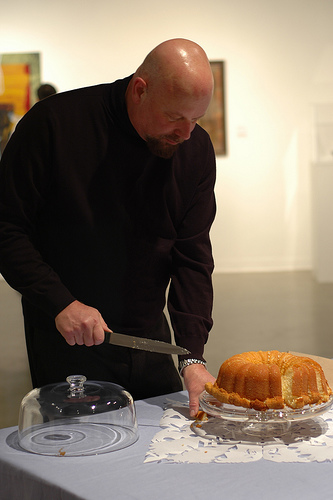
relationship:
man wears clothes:
[1, 37, 221, 422] [1, 74, 217, 425]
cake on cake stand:
[203, 349, 332, 412] [198, 390, 332, 435]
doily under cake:
[145, 396, 333, 465] [203, 349, 332, 412]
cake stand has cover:
[198, 390, 332, 435] [18, 374, 139, 456]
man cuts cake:
[1, 37, 221, 422] [203, 349, 332, 412]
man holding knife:
[1, 37, 221, 422] [104, 331, 190, 357]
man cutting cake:
[1, 37, 221, 422] [203, 349, 332, 412]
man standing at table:
[1, 37, 221, 422] [1, 381, 331, 498]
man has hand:
[1, 37, 221, 422] [53, 299, 115, 346]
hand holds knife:
[53, 299, 115, 346] [104, 331, 190, 357]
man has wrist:
[1, 37, 221, 422] [176, 356, 210, 376]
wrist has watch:
[176, 356, 210, 376] [178, 358, 206, 374]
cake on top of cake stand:
[203, 349, 332, 412] [198, 390, 332, 435]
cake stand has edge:
[198, 390, 332, 435] [227, 409, 327, 423]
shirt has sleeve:
[2, 71, 217, 365] [167, 130, 216, 365]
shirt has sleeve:
[2, 71, 217, 365] [1, 97, 80, 322]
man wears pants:
[1, 37, 221, 422] [21, 295, 184, 423]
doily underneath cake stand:
[145, 396, 333, 465] [198, 390, 332, 435]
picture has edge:
[196, 61, 227, 159] [220, 60, 228, 157]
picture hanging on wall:
[196, 61, 227, 159] [1, 1, 333, 273]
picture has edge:
[1, 52, 40, 156] [36, 52, 42, 106]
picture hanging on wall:
[1, 52, 40, 156] [1, 1, 333, 273]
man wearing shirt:
[1, 37, 221, 422] [2, 71, 217, 365]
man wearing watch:
[1, 37, 221, 422] [178, 358, 206, 374]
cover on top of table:
[18, 374, 139, 456] [1, 381, 331, 498]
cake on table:
[203, 349, 332, 412] [1, 381, 331, 498]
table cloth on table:
[1, 374, 333, 499] [1, 381, 331, 498]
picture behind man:
[196, 61, 227, 159] [1, 37, 221, 422]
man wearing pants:
[1, 37, 221, 422] [21, 295, 184, 423]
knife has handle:
[104, 331, 190, 357] [103, 331, 113, 343]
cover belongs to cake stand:
[18, 374, 139, 456] [198, 390, 332, 435]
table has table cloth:
[1, 381, 331, 498] [1, 374, 333, 499]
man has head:
[1, 37, 221, 422] [124, 37, 213, 158]